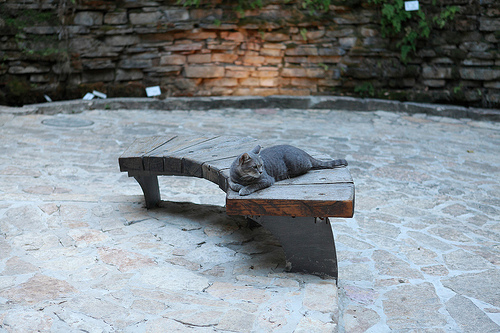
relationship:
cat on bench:
[229, 144, 349, 196] [115, 120, 362, 296]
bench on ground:
[118, 127, 359, 281] [1, 90, 494, 331]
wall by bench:
[4, 2, 499, 115] [115, 120, 362, 296]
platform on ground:
[113, 120, 371, 276] [1, 90, 494, 331]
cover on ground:
[40, 115, 95, 127] [1, 90, 494, 331]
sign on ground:
[141, 80, 177, 101] [1, 90, 494, 331]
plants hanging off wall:
[6, 0, 495, 67] [4, 2, 499, 115]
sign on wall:
[406, 0, 418, 19] [4, 2, 499, 115]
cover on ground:
[40, 115, 95, 127] [2, 131, 116, 312]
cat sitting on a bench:
[229, 144, 349, 196] [111, 120, 365, 275]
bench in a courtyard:
[118, 127, 359, 281] [7, 2, 494, 330]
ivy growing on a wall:
[385, 3, 466, 65] [126, 0, 488, 109]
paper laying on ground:
[69, 85, 108, 109] [37, 118, 292, 138]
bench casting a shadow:
[118, 127, 359, 281] [210, 215, 262, 269]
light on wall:
[224, 58, 284, 98] [37, 11, 464, 103]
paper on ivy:
[399, 0, 420, 18] [385, 2, 469, 53]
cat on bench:
[229, 144, 349, 196] [118, 127, 359, 281]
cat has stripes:
[222, 139, 347, 189] [309, 153, 348, 170]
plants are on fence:
[376, 3, 458, 46] [212, 6, 483, 91]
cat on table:
[229, 144, 349, 196] [117, 122, 358, 282]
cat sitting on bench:
[229, 144, 349, 196] [118, 127, 359, 281]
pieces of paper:
[79, 81, 168, 99] [68, 87, 169, 101]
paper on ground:
[68, 87, 169, 101] [369, 130, 470, 310]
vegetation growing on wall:
[285, 0, 340, 20] [50, 12, 482, 90]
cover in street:
[40, 110, 97, 131] [10, 130, 115, 325]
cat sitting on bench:
[229, 144, 349, 196] [114, 137, 354, 271]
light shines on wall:
[184, 28, 295, 98] [1, 11, 462, 86]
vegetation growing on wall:
[374, 4, 484, 45] [12, 8, 484, 98]